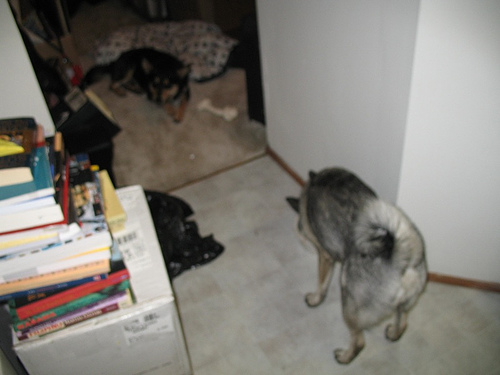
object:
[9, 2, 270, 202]
door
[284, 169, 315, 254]
looking down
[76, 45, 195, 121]
man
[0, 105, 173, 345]
books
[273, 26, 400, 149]
wall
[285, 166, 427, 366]
animal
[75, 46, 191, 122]
animal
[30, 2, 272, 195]
carpet floor